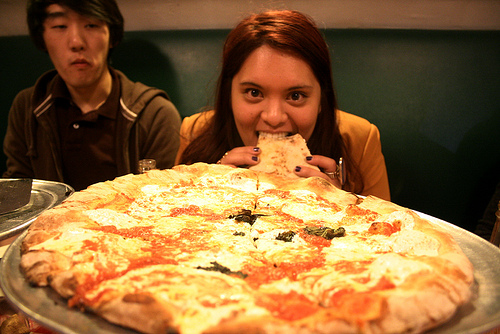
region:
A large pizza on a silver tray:
[18, 150, 494, 332]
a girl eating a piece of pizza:
[168, 2, 384, 193]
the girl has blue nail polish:
[234, 142, 324, 177]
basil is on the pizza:
[193, 206, 345, 279]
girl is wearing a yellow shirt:
[167, 96, 392, 207]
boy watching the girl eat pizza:
[9, 1, 398, 215]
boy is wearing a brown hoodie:
[3, 68, 179, 192]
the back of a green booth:
[2, 20, 499, 243]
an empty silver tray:
[0, 173, 73, 244]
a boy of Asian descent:
[15, 0, 134, 107]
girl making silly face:
[169, 3, 392, 205]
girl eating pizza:
[164, 2, 396, 199]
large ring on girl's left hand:
[324, 154, 349, 183]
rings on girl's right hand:
[215, 148, 228, 163]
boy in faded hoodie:
[4, 0, 180, 182]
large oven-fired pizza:
[19, 153, 475, 331]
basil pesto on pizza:
[200, 200, 348, 280]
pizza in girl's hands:
[246, 128, 317, 183]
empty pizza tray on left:
[1, 159, 75, 241]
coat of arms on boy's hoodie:
[133, 152, 157, 173]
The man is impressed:
[32, 8, 129, 91]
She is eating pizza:
[187, 33, 349, 178]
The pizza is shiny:
[78, 166, 434, 310]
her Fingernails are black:
[288, 153, 314, 168]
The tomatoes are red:
[267, 292, 303, 313]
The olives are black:
[280, 222, 345, 242]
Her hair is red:
[215, 20, 330, 55]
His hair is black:
[20, 7, 128, 45]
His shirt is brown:
[70, 118, 112, 170]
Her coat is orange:
[190, 112, 394, 147]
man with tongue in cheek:
[30, 1, 120, 86]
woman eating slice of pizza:
[223, 8, 328, 148]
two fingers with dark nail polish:
[230, 145, 262, 164]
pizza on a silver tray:
[5, 168, 499, 333]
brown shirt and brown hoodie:
[7, 78, 177, 175]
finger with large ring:
[305, 150, 352, 187]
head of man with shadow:
[18, 1, 187, 94]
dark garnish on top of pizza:
[230, 201, 351, 244]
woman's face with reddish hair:
[215, 5, 328, 129]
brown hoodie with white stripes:
[13, 69, 170, 169]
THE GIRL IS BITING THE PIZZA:
[250, 128, 300, 148]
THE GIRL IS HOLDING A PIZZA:
[212, 135, 342, 190]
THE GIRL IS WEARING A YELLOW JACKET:
[160, 97, 396, 210]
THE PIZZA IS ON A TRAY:
[12, 151, 478, 331]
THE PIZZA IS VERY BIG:
[0, 168, 496, 330]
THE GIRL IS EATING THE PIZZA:
[180, 5, 366, 201]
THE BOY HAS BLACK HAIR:
[12, 0, 133, 83]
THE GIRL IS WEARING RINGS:
[211, 151, 231, 171]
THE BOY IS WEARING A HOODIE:
[3, 68, 183, 186]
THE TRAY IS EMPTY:
[0, 164, 78, 243]